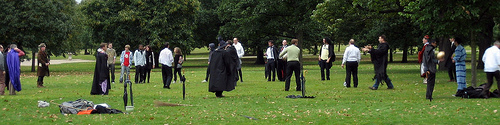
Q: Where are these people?
A: A park.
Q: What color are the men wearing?
A: Black and White.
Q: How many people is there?
A: 23.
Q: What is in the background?
A: Trees.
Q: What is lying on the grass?
A: Clothes.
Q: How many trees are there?
A: 6.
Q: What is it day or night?
A: Day.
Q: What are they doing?
A: Playing a game.